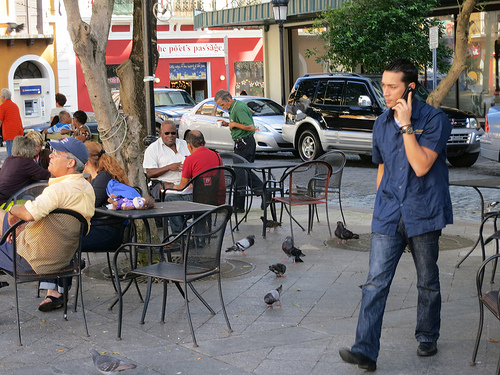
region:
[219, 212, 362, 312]
a group of pigeons on the ground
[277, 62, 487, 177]
a black SUV parked on the curb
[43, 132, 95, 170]
a blue baseball cap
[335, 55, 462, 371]
a man walking and talking on the phone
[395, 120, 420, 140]
a watch on someone's wrist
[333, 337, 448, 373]
black boots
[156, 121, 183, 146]
man wearing black sunglasses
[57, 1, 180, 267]
a tree between the tables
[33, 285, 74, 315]
a black flip flop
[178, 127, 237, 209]
a balding man in a red shirt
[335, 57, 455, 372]
Man talking on cell phone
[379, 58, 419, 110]
Face of man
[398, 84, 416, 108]
Black cell phone that the man is talking on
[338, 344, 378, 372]
Black shoe of man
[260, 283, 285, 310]
Bird walking on the ground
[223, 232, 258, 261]
Bird walking on the ground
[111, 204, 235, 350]
Black four legged chair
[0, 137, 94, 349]
Man in chair staring off into the distance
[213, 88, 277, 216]
Man walking and looking at ground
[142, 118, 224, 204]
Two men talking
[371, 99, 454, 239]
he wears a blue shirt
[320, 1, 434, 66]
the branches of the tree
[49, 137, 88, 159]
this is a blue cap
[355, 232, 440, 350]
he is wearing a blue jeans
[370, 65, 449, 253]
he is on the phone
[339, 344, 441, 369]
a couple of black shoes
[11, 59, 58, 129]
this is an ATM machine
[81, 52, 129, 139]
the thick trunk of the tree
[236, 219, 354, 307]
several pigeons eating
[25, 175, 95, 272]
he is wearing a yellow shirt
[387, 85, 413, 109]
man is holding a phone.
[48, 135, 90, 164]
blue cap on man's head.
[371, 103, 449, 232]
man is wearing a navy shirt.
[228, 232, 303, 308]
pigeons on the sidewalk.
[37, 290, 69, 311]
person is wearing sandals.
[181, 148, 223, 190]
man has on a red shirt.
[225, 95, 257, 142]
the man is wearing green.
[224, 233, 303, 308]
four pigeons on ground.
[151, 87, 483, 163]
vehicles in the background.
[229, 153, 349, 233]
black metal table and chairs.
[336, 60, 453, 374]
man holding a cellphone with left hand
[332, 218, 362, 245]
pigeon standing on manhole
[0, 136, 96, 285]
man wearing a blue cap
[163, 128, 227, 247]
man sitting on metal chair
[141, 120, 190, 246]
man next to the tree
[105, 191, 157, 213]
doll on the metal table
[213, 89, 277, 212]
man walking on the sidewalk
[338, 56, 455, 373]
young man wearing blue jeans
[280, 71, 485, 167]
car parked beside tree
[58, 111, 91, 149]
person sitting on bench